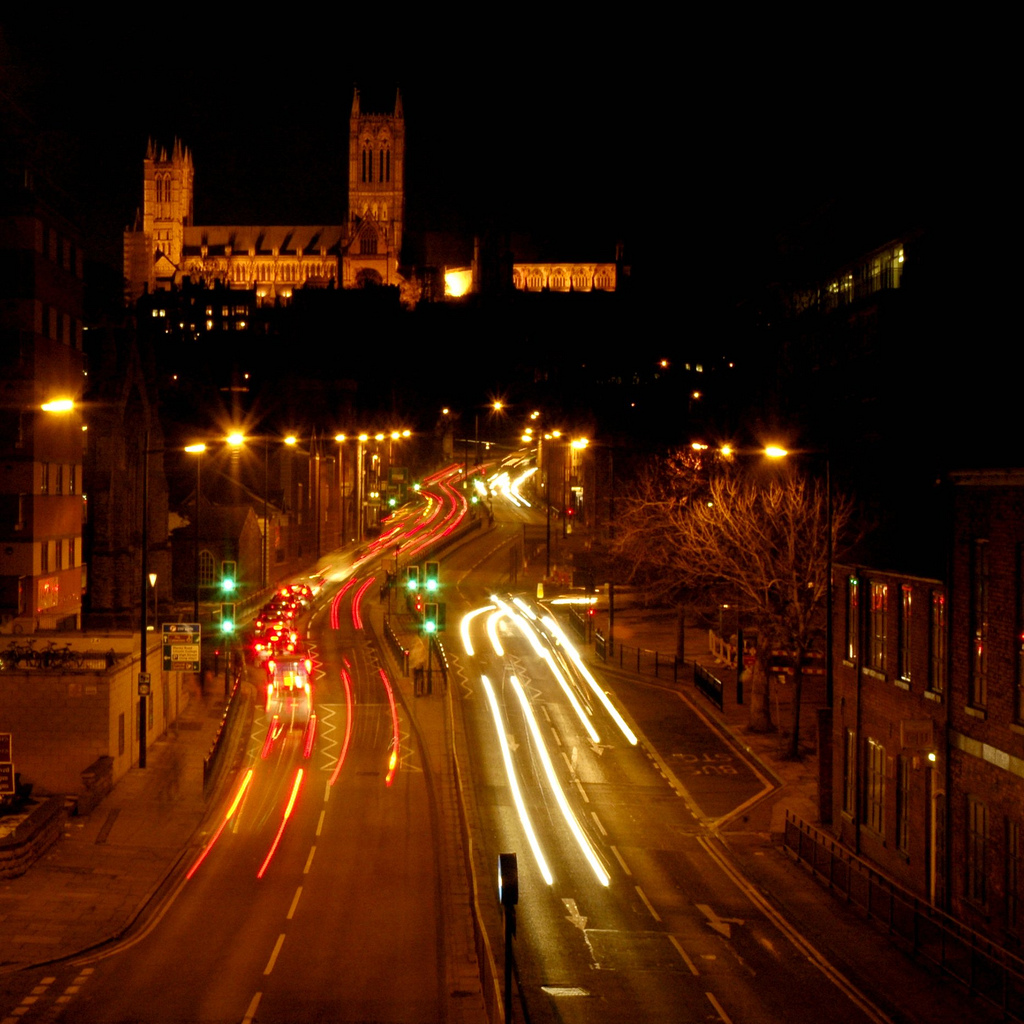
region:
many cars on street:
[177, 426, 658, 815]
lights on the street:
[364, 568, 659, 957]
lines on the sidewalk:
[223, 821, 382, 993]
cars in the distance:
[372, 423, 518, 564]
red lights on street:
[228, 635, 384, 765]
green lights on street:
[366, 540, 491, 667]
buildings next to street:
[6, 392, 191, 746]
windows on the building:
[792, 563, 974, 696]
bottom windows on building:
[793, 705, 959, 895]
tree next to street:
[637, 497, 849, 676]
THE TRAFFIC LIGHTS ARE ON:
[393, 517, 458, 673]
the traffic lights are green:
[378, 538, 474, 656]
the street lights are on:
[643, 378, 828, 628]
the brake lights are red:
[188, 522, 372, 839]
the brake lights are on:
[247, 525, 340, 786]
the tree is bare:
[655, 460, 833, 642]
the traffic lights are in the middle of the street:
[389, 538, 457, 668]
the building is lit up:
[77, 102, 613, 308]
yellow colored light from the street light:
[21, 374, 95, 429]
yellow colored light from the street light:
[213, 415, 258, 454]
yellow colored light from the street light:
[557, 416, 597, 464]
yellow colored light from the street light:
[753, 427, 808, 473]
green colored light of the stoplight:
[418, 567, 442, 612]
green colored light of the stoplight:
[217, 563, 231, 596]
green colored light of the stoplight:
[420, 611, 446, 644]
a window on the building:
[871, 742, 909, 838]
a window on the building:
[842, 742, 859, 847]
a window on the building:
[816, 715, 871, 820]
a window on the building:
[904, 578, 939, 677]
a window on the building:
[825, 589, 857, 670]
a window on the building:
[942, 595, 971, 729]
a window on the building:
[953, 783, 993, 879]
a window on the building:
[40, 522, 86, 609]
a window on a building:
[29, 459, 40, 498]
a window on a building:
[50, 453, 61, 495]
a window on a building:
[65, 468, 76, 497]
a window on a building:
[32, 536, 40, 576]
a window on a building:
[68, 536, 87, 562]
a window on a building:
[114, 706, 127, 752]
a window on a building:
[145, 683, 158, 731]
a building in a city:
[19, 390, 90, 635]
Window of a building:
[838, 572, 864, 661]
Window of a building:
[862, 579, 891, 668]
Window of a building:
[897, 581, 913, 687]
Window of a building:
[926, 587, 952, 702]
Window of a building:
[893, 753, 912, 852]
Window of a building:
[843, 730, 856, 819]